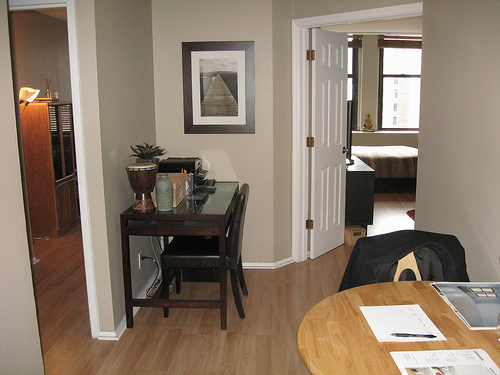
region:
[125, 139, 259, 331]
Computer desk in the hall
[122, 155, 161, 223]
A bongo drum on the table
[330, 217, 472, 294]
Suit jacket on chair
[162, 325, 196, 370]
Light brown wood flooring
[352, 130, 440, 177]
Bed inside bed room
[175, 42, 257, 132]
Picture hanging on wall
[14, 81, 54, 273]
Lamp standing on floor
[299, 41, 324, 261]
Hinges on the door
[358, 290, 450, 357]
Paper and pen on table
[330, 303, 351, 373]
Wood grain table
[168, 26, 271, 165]
picture frame hanging above desk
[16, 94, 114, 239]
the cabinet is made of wood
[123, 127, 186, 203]
plant is on the desk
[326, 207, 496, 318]
black jacket on chair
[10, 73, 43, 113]
lamp is turned on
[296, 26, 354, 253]
the door is open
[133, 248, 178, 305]
black cord plugged in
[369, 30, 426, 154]
window frame is brown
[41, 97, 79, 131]
reflection of window on cabinet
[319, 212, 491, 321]
the jacket is black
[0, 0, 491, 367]
Photo taken in a hallway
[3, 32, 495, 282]
The walls are painted beige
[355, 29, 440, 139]
Sunlight coming in through a window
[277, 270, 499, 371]
Round table in the right corner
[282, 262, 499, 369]
Table in the bottom right is made of wood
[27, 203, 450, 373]
The floor is made of wood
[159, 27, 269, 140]
A painting hanging on the wall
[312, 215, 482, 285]
A black jacket hanging over a chair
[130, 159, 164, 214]
A drum on the rectangle table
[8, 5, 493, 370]
Nobody shown in the photo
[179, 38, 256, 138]
framed picture on wall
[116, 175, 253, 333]
brown desk and chair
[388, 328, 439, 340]
ink pen laying on table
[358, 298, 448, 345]
white paper laying on table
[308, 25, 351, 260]
white door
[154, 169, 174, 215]
small vase sitting on desk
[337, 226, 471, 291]
black jacket on back of chair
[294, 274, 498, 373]
round wood table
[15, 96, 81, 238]
wood cabinet in hallway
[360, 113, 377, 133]
small Buddha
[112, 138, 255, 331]
Dark wood table and chair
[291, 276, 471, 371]
Light wood tabletop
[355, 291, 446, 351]
Black pen and white piece of paper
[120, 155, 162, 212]
Large brown vase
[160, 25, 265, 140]
Picture on the wall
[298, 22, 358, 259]
White door between rooms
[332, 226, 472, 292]
Jacket hanging on the back of a chair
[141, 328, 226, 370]
Light brown wood floors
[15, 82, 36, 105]
Light from a small lamp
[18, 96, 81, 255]
Brown wood entertainment center